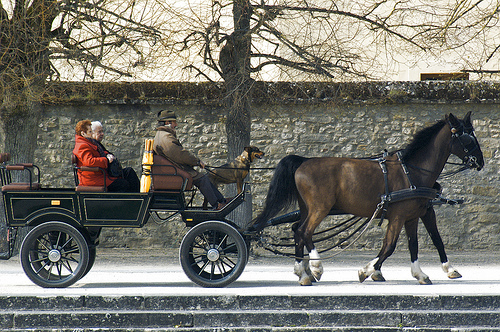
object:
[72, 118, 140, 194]
woman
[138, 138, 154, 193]
umbrellas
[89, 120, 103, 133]
hair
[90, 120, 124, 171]
man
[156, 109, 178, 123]
hat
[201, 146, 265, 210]
dog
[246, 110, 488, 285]
horse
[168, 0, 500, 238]
tree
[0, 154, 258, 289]
buggy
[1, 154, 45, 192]
seat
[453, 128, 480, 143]
blinder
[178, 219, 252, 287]
wheels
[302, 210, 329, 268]
legs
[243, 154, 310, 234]
tail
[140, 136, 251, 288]
chariot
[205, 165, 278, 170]
belts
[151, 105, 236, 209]
men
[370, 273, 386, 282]
horseshoe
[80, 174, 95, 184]
red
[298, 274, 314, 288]
hooves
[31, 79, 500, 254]
wall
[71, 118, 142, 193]
couple